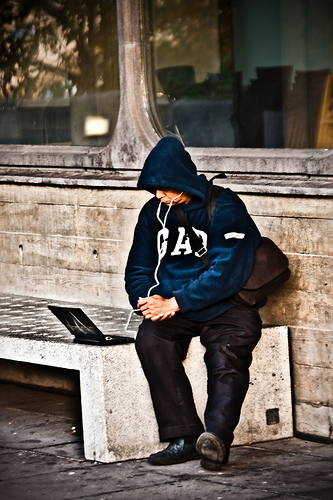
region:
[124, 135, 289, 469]
man sitting on a park bench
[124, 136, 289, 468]
man using a laptop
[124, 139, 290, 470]
man wearing a white headphones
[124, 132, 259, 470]
man with a brown satchel on his arm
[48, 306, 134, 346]
black laptop on the bench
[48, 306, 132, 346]
black laptop that is open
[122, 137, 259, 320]
blue hoodie with white letters on it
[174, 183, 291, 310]
brown satchel on the man's arm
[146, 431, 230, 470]
black shoes on the man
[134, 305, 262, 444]
brown pants on the man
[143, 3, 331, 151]
large window of building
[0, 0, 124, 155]
large window of building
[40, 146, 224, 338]
man looking at electronic device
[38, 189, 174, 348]
earphones plugged into electronic device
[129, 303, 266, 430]
man wearing black pants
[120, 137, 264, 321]
man wearing gap hoodie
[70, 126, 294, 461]
man sitting on bench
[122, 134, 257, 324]
man wearing a hoodie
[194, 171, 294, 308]
man's black shoulder bag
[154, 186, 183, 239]
man wearing white earphones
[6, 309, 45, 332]
Top surface of concrete bench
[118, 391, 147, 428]
Leg of a concrete bench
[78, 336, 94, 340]
A black lap top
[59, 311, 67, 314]
Front cover of lap top open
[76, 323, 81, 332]
Chalk marks on lap top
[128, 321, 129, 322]
White cable plugged in lap top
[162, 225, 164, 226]
Cable with ear phones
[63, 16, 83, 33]
Reflection of tree on a window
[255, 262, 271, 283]
A black satchet under the arm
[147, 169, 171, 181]
A hood on the head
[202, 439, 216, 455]
Sole of foot raised up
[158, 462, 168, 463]
Mud on side of shoe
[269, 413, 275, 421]
Rectangular hole on bench leg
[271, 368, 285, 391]
Side of bench with marks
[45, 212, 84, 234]
Paint on whitewashed wall fading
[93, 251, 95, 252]
A hole in the wall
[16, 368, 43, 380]
Wall surface under the bench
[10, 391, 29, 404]
The floor under the bench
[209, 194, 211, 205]
Strap over the shoulder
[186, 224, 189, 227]
Strap across the chest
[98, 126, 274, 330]
person wearing hooded shirt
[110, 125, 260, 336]
shirt has long sleeves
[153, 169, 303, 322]
person wearing cross body satchel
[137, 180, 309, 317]
cross body satchel is black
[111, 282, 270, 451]
person wearing black pants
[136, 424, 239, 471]
person wearing black shoes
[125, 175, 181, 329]
person wearing pair of headphones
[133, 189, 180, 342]
headphone set is white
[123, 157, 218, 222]
person head positioned down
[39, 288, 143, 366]
open laptop is black